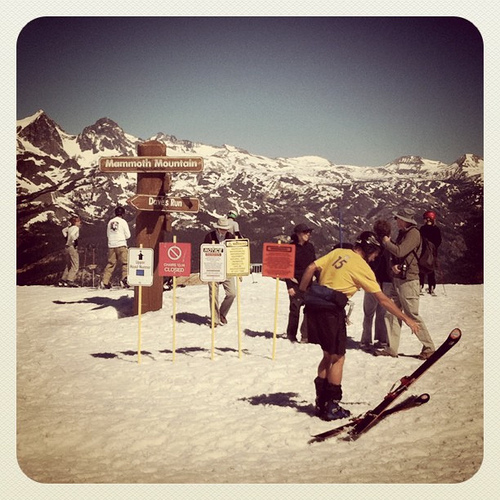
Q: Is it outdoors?
A: Yes, it is outdoors.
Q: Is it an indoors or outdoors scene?
A: It is outdoors.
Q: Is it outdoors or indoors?
A: It is outdoors.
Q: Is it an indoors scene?
A: No, it is outdoors.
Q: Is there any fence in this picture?
A: No, there are no fences.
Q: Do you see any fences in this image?
A: No, there are no fences.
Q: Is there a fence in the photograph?
A: No, there are no fences.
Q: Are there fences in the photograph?
A: No, there are no fences.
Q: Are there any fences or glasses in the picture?
A: No, there are no fences or glasses.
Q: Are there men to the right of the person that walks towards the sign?
A: Yes, there is a man to the right of the person.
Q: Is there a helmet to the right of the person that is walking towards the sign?
A: No, there is a man to the right of the person.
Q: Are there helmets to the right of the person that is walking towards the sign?
A: No, there is a man to the right of the person.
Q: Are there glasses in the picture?
A: No, there are no glasses.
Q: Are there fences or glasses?
A: No, there are no glasses or fences.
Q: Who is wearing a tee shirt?
A: The man is wearing a tee shirt.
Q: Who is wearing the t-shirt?
A: The man is wearing a tee shirt.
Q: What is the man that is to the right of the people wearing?
A: The man is wearing a t-shirt.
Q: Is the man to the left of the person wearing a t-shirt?
A: Yes, the man is wearing a t-shirt.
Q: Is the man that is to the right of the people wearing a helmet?
A: No, the man is wearing a t-shirt.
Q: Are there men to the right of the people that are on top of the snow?
A: Yes, there is a man to the right of the people.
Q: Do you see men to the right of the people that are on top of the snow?
A: Yes, there is a man to the right of the people.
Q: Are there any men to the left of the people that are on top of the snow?
A: No, the man is to the right of the people.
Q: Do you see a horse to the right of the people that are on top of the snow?
A: No, there is a man to the right of the people.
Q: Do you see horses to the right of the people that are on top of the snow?
A: No, there is a man to the right of the people.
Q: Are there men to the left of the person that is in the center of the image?
A: Yes, there is a man to the left of the person.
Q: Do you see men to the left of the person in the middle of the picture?
A: Yes, there is a man to the left of the person.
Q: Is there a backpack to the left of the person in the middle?
A: No, there is a man to the left of the person.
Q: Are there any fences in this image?
A: No, there are no fences.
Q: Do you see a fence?
A: No, there are no fences.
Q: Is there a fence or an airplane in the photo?
A: No, there are no fences or airplanes.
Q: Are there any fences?
A: No, there are no fences.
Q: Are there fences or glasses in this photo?
A: No, there are no fences or glasses.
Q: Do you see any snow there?
A: Yes, there is snow.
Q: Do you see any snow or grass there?
A: Yes, there is snow.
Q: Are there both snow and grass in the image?
A: No, there is snow but no grass.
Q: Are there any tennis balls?
A: No, there are no tennis balls.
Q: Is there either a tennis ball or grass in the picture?
A: No, there are no tennis balls or grass.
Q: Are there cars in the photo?
A: No, there are no cars.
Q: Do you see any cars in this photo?
A: No, there are no cars.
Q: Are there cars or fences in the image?
A: No, there are no cars or fences.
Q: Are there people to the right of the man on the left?
A: Yes, there is a person to the right of the man.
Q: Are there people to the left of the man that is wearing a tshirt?
A: No, the person is to the right of the man.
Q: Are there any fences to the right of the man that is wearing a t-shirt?
A: No, there is a person to the right of the man.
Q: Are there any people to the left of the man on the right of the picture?
A: Yes, there is a person to the left of the man.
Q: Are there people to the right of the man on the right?
A: No, the person is to the left of the man.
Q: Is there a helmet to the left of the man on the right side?
A: No, there is a person to the left of the man.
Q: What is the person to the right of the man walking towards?
A: The person is walking towards the sign.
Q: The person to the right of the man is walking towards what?
A: The person is walking towards the sign.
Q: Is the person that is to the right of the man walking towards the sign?
A: Yes, the person is walking towards the sign.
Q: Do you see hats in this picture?
A: Yes, there is a hat.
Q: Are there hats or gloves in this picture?
A: Yes, there is a hat.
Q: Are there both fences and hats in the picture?
A: No, there is a hat but no fences.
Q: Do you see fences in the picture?
A: No, there are no fences.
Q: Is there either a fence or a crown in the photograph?
A: No, there are no fences or crowns.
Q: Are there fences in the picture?
A: No, there are no fences.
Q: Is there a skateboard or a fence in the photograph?
A: No, there are no fences or skateboards.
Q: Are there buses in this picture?
A: No, there are no buses.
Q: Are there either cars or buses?
A: No, there are no buses or cars.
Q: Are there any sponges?
A: No, there are no sponges.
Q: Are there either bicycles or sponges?
A: No, there are no sponges or bicycles.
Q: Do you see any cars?
A: No, there are no cars.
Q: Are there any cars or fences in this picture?
A: No, there are no cars or fences.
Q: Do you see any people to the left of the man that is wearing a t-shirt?
A: Yes, there are people to the left of the man.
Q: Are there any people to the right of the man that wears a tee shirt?
A: No, the people are to the left of the man.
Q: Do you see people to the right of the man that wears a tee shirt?
A: No, the people are to the left of the man.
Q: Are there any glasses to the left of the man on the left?
A: No, there are people to the left of the man.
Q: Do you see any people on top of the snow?
A: Yes, there are people on top of the snow.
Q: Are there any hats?
A: Yes, there is a hat.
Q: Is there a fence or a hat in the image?
A: Yes, there is a hat.